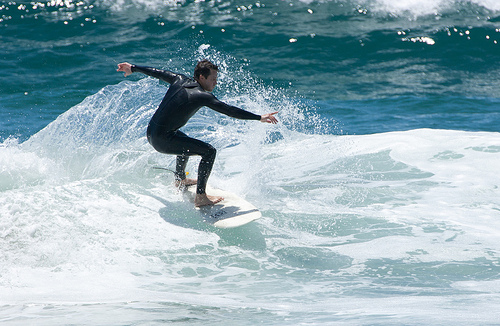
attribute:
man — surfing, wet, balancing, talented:
[108, 44, 273, 194]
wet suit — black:
[145, 63, 240, 175]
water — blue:
[367, 120, 408, 152]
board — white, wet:
[211, 209, 269, 237]